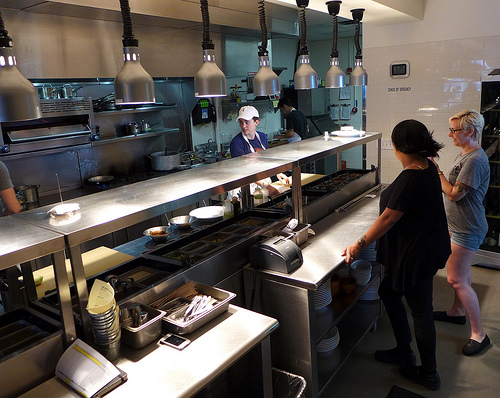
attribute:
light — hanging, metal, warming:
[114, 37, 156, 105]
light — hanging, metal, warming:
[193, 43, 229, 99]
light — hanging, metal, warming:
[253, 49, 280, 99]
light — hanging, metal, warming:
[293, 50, 319, 91]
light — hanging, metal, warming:
[324, 53, 347, 87]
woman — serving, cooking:
[229, 105, 291, 198]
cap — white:
[235, 104, 259, 121]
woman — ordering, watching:
[341, 118, 453, 391]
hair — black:
[391, 119, 445, 160]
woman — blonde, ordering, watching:
[430, 108, 492, 358]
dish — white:
[192, 206, 230, 223]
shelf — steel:
[0, 126, 384, 271]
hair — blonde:
[447, 109, 485, 146]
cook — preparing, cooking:
[277, 96, 309, 145]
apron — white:
[287, 129, 303, 145]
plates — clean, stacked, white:
[312, 278, 333, 313]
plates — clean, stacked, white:
[315, 325, 340, 354]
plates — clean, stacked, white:
[357, 273, 380, 302]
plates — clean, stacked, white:
[358, 233, 378, 261]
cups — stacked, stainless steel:
[90, 302, 122, 361]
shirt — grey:
[442, 146, 491, 237]